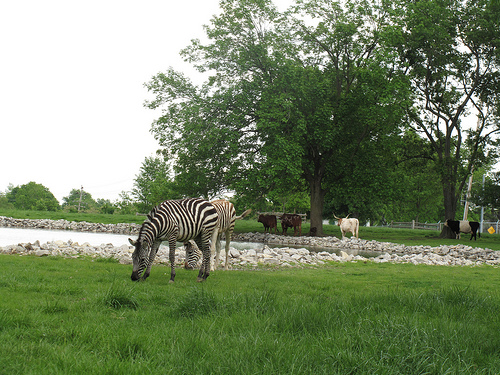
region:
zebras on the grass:
[112, 178, 274, 290]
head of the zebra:
[121, 235, 157, 280]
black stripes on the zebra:
[146, 201, 201, 241]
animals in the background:
[255, 200, 310, 240]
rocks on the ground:
[260, 237, 315, 272]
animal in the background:
[326, 206, 362, 236]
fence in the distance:
[400, 212, 430, 232]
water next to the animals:
[0, 225, 92, 245]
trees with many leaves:
[261, 125, 406, 200]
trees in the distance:
[12, 171, 108, 234]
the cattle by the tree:
[250, 204, 371, 241]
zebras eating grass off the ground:
[127, 191, 241, 291]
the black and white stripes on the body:
[149, 201, 211, 233]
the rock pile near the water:
[10, 231, 122, 263]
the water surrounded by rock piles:
[7, 218, 109, 260]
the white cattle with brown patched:
[330, 209, 362, 240]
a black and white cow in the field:
[440, 215, 482, 240]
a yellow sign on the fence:
[486, 224, 494, 237]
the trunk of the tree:
[299, 141, 329, 237]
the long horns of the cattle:
[328, 209, 353, 221]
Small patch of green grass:
[255, 328, 276, 353]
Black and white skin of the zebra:
[168, 208, 198, 231]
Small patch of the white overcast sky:
[63, 105, 86, 138]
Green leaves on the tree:
[178, 114, 207, 139]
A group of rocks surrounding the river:
[265, 248, 287, 263]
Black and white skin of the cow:
[451, 218, 472, 230]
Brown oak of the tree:
[310, 209, 319, 227]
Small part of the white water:
[17, 230, 33, 242]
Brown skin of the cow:
[266, 216, 275, 224]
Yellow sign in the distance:
[486, 223, 497, 238]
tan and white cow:
[332, 209, 362, 239]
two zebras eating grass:
[120, 193, 245, 288]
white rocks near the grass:
[248, 245, 308, 281]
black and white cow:
[440, 215, 482, 238]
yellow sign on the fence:
[480, 220, 498, 239]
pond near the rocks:
[15, 225, 54, 246]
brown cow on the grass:
[276, 210, 302, 234]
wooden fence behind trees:
[385, 218, 440, 231]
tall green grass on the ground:
[173, 287, 224, 323]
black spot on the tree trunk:
[307, 223, 319, 236]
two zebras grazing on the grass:
[124, 190, 247, 288]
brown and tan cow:
[329, 205, 366, 242]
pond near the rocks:
[27, 227, 88, 247]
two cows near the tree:
[255, 209, 306, 234]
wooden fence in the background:
[385, 213, 442, 235]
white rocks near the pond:
[22, 240, 98, 257]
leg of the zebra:
[157, 240, 183, 285]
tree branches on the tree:
[413, 127, 480, 215]